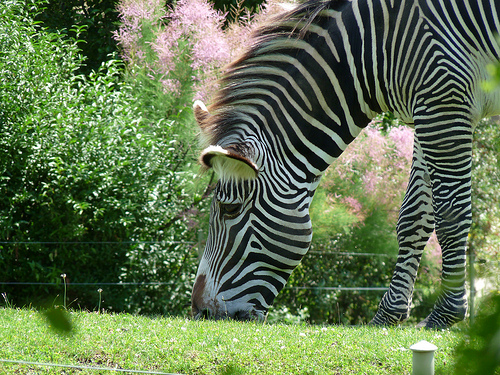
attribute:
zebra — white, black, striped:
[186, 0, 499, 332]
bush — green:
[4, 2, 201, 315]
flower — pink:
[115, 4, 428, 204]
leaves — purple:
[1, 4, 200, 316]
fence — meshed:
[1, 240, 499, 325]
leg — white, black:
[415, 112, 480, 334]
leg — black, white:
[365, 140, 430, 325]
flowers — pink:
[115, 0, 167, 61]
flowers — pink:
[147, 13, 189, 96]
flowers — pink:
[197, 16, 254, 102]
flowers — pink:
[327, 122, 394, 212]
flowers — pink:
[378, 119, 414, 210]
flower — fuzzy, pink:
[160, 22, 225, 82]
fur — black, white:
[232, 38, 352, 105]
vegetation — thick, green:
[0, 6, 195, 316]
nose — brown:
[182, 265, 214, 315]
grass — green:
[102, 304, 228, 369]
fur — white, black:
[192, 1, 497, 331]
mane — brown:
[202, 19, 294, 149]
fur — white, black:
[182, 12, 496, 311]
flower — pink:
[112, 4, 155, 48]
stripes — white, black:
[189, 2, 496, 319]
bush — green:
[1, 4, 217, 332]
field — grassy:
[2, 304, 498, 374]